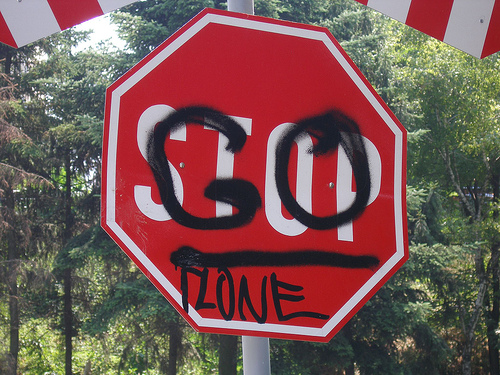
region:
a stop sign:
[71, 6, 428, 354]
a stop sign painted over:
[97, 5, 427, 350]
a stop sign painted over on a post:
[89, 3, 424, 370]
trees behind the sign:
[13, 68, 85, 365]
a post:
[225, 339, 285, 368]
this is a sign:
[3, 0, 490, 373]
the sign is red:
[73, 14, 454, 343]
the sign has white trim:
[86, 13, 451, 357]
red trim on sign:
[76, 4, 420, 361]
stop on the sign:
[117, 85, 384, 272]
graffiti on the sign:
[139, 82, 376, 338]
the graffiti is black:
[135, 77, 377, 300]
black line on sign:
[169, 216, 394, 296]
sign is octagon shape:
[65, 18, 446, 353]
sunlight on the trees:
[25, 318, 141, 369]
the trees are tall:
[8, 67, 110, 368]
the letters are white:
[136, 112, 347, 242]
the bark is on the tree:
[61, 155, 80, 370]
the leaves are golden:
[377, 26, 457, 102]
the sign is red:
[116, 14, 398, 344]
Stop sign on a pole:
[104, 7, 404, 343]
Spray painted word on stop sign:
[137, 98, 367, 228]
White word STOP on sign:
[127, 100, 377, 249]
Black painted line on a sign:
[147, 241, 389, 265]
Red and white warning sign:
[5, 0, 120, 54]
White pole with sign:
[240, 335, 275, 372]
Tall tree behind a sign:
[32, 56, 89, 373]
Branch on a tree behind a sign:
[435, 147, 472, 219]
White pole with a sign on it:
[222, 1, 262, 16]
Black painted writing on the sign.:
[152, 106, 357, 263]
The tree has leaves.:
[416, 92, 463, 139]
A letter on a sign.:
[136, 87, 187, 238]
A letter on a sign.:
[268, 115, 329, 222]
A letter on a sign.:
[323, 124, 388, 263]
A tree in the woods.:
[27, 55, 139, 373]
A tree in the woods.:
[103, 43, 208, 371]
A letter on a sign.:
[93, 80, 194, 242]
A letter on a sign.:
[202, 98, 242, 248]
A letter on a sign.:
[336, 114, 381, 271]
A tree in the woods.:
[31, 97, 101, 373]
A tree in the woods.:
[86, 52, 182, 358]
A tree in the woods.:
[353, 190, 410, 352]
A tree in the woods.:
[16, 35, 106, 374]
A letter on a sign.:
[142, 77, 190, 241]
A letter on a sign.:
[203, 100, 240, 238]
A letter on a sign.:
[263, 115, 300, 247]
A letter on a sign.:
[326, 130, 375, 245]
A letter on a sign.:
[169, 99, 237, 211]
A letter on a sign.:
[183, 259, 211, 312]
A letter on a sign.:
[233, 267, 266, 319]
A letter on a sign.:
[271, 260, 314, 333]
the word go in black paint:
[144, 101, 371, 228]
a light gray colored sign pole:
[238, 333, 273, 374]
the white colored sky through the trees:
[28, 11, 135, 68]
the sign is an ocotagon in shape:
[100, 3, 408, 345]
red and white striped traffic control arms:
[0, 0, 498, 60]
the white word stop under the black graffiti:
[136, 103, 386, 242]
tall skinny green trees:
[1, 1, 498, 372]